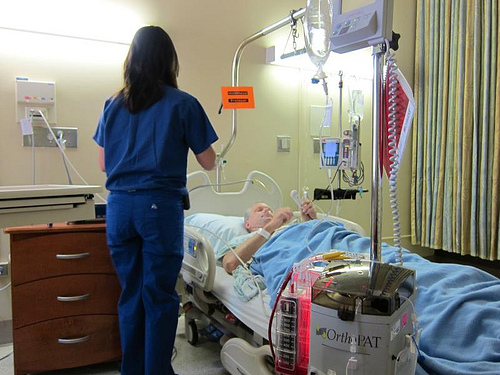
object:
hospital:
[0, 0, 500, 375]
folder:
[379, 60, 416, 181]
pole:
[368, 49, 384, 275]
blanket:
[247, 218, 499, 373]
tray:
[0, 184, 94, 216]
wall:
[0, 2, 415, 259]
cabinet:
[0, 219, 124, 375]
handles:
[52, 251, 95, 344]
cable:
[384, 46, 403, 267]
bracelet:
[255, 227, 272, 240]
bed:
[178, 178, 499, 372]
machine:
[268, 261, 316, 375]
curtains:
[407, 0, 499, 262]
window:
[407, 0, 498, 265]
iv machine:
[214, 0, 402, 375]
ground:
[0, 300, 234, 375]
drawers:
[1, 230, 134, 374]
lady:
[92, 24, 218, 375]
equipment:
[265, 249, 421, 375]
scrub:
[90, 82, 218, 375]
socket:
[21, 126, 80, 149]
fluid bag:
[301, 1, 333, 84]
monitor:
[290, 189, 309, 207]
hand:
[299, 200, 317, 222]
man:
[221, 201, 500, 375]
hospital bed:
[178, 199, 500, 375]